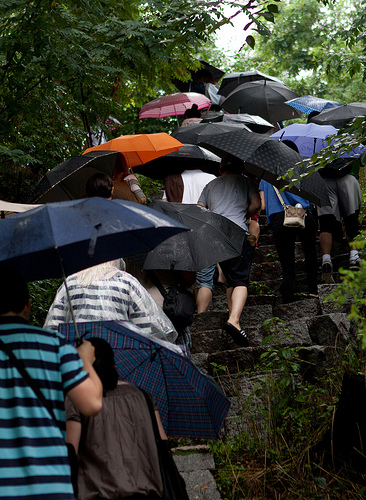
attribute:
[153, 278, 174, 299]
shoulder — person's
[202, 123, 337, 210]
umbrella — black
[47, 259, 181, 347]
coat — clear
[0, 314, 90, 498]
shirt — striped, blue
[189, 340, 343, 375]
step — stone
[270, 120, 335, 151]
blue umbrella — open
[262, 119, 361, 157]
umbrella — light, blue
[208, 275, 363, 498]
grass — green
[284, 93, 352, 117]
umbrella — blue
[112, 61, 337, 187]
wet umbrellas — open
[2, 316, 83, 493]
black shirt — blue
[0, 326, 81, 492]
shirt — blue and black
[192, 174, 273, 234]
shirt — striped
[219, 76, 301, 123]
umbrella — black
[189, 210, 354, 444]
steps — leading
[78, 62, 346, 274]
people — walking